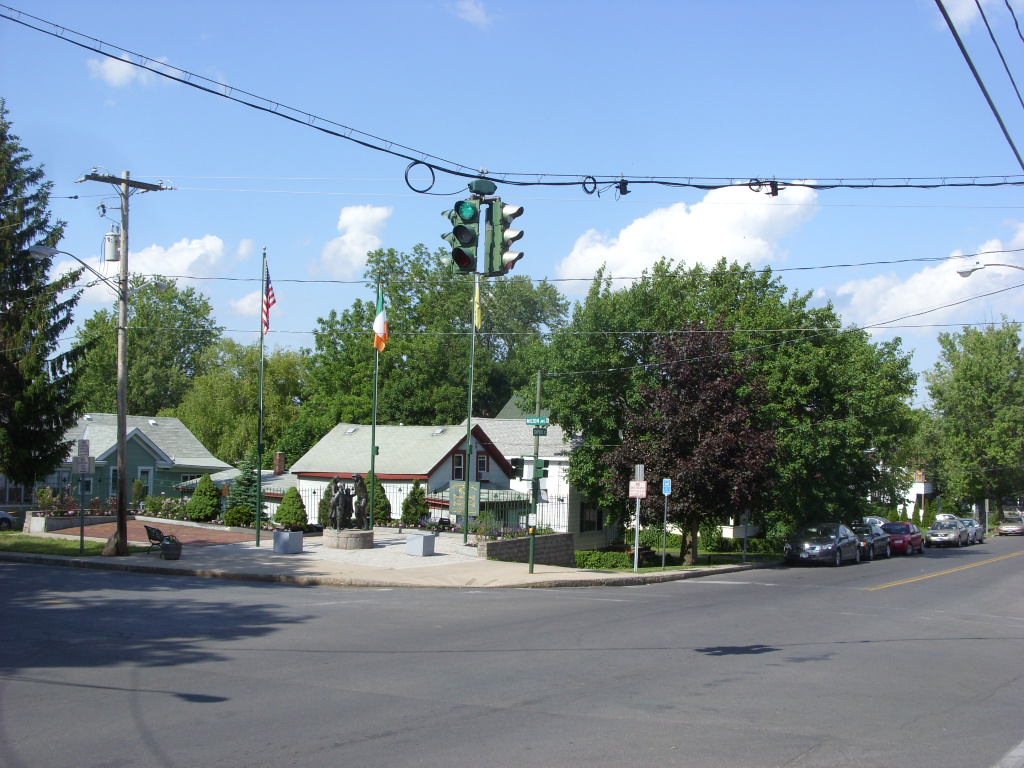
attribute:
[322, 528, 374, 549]
base — round